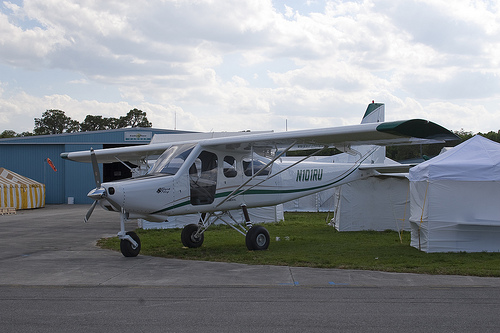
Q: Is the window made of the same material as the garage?
A: No, the window is made of glass and the garage is made of metal.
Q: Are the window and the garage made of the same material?
A: No, the window is made of glass and the garage is made of metal.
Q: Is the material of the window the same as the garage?
A: No, the window is made of glass and the garage is made of metal.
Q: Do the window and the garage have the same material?
A: No, the window is made of glass and the garage is made of metal.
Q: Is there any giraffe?
A: No, there are no giraffes.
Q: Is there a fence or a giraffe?
A: No, there are no giraffes or fences.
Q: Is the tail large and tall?
A: Yes, the tail is large and tall.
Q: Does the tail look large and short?
A: No, the tail is large but tall.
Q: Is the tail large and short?
A: No, the tail is large but tall.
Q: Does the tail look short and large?
A: No, the tail is large but tall.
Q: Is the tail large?
A: Yes, the tail is large.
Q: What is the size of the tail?
A: The tail is large.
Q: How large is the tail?
A: The tail is large.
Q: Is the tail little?
A: No, the tail is large.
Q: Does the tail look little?
A: No, the tail is large.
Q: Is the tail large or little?
A: The tail is large.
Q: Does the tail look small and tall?
A: No, the tail is tall but large.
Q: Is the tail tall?
A: Yes, the tail is tall.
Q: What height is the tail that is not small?
A: The tail is tall.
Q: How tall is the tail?
A: The tail is tall.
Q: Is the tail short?
A: No, the tail is tall.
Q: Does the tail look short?
A: No, the tail is tall.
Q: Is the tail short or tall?
A: The tail is tall.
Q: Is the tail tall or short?
A: The tail is tall.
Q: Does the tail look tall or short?
A: The tail is tall.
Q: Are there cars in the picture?
A: No, there are no cars.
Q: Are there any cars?
A: No, there are no cars.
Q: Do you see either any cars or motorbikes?
A: No, there are no cars or motorbikes.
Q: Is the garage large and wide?
A: Yes, the garage is large and wide.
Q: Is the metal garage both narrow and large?
A: No, the garage is large but wide.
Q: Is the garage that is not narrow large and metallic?
A: Yes, the garage is large and metallic.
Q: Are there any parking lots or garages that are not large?
A: No, there is a garage but it is large.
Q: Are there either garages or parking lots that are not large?
A: No, there is a garage but it is large.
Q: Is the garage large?
A: Yes, the garage is large.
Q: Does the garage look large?
A: Yes, the garage is large.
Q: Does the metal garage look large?
A: Yes, the garage is large.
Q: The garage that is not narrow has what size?
A: The garage is large.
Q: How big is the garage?
A: The garage is large.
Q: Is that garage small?
A: No, the garage is large.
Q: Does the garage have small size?
A: No, the garage is large.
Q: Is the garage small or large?
A: The garage is large.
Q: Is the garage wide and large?
A: Yes, the garage is wide and large.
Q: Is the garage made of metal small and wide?
A: No, the garage is wide but large.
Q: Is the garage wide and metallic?
A: Yes, the garage is wide and metallic.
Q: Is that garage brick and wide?
A: No, the garage is wide but metallic.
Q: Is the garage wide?
A: Yes, the garage is wide.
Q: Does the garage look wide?
A: Yes, the garage is wide.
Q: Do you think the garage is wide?
A: Yes, the garage is wide.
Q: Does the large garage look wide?
A: Yes, the garage is wide.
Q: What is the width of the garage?
A: The garage is wide.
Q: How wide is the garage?
A: The garage is wide.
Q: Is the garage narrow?
A: No, the garage is wide.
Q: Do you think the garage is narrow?
A: No, the garage is wide.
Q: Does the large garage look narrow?
A: No, the garage is wide.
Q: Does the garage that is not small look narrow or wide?
A: The garage is wide.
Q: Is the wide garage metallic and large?
A: Yes, the garage is metallic and large.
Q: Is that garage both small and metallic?
A: No, the garage is metallic but large.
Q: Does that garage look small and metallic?
A: No, the garage is metallic but large.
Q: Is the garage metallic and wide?
A: Yes, the garage is metallic and wide.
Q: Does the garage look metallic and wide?
A: Yes, the garage is metallic and wide.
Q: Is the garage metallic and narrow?
A: No, the garage is metallic but wide.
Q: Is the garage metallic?
A: Yes, the garage is metallic.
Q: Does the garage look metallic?
A: Yes, the garage is metallic.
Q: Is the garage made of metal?
A: Yes, the garage is made of metal.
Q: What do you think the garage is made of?
A: The garage is made of metal.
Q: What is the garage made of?
A: The garage is made of metal.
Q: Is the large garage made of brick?
A: No, the garage is made of metal.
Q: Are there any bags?
A: No, there are no bags.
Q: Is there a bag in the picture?
A: No, there are no bags.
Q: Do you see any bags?
A: No, there are no bags.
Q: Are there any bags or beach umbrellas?
A: No, there are no bags or beach umbrellas.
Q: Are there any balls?
A: No, there are no balls.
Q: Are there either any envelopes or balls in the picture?
A: No, there are no balls or envelopes.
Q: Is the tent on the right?
A: Yes, the tent is on the right of the image.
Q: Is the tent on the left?
A: No, the tent is on the right of the image.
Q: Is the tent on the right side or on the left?
A: The tent is on the right of the image.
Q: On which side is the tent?
A: The tent is on the right of the image.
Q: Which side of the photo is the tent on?
A: The tent is on the right of the image.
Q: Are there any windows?
A: Yes, there is a window.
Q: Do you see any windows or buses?
A: Yes, there is a window.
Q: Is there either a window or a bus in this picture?
A: Yes, there is a window.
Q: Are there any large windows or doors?
A: Yes, there is a large window.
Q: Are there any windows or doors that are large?
A: Yes, the window is large.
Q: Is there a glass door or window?
A: Yes, there is a glass window.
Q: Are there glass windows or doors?
A: Yes, there is a glass window.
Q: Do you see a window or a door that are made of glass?
A: Yes, the window is made of glass.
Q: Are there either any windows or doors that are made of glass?
A: Yes, the window is made of glass.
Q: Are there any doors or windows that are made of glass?
A: Yes, the window is made of glass.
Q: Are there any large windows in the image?
A: Yes, there is a large window.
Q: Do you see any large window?
A: Yes, there is a large window.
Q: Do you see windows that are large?
A: Yes, there is a window that is large.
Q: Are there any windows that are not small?
A: Yes, there is a large window.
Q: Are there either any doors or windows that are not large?
A: No, there is a window but it is large.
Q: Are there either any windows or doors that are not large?
A: No, there is a window but it is large.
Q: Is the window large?
A: Yes, the window is large.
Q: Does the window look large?
A: Yes, the window is large.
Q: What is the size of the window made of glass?
A: The window is large.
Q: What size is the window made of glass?
A: The window is large.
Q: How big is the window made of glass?
A: The window is large.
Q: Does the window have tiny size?
A: No, the window is large.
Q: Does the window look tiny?
A: No, the window is large.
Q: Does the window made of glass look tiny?
A: No, the window is large.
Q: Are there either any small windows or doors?
A: No, there is a window but it is large.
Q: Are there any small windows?
A: No, there is a window but it is large.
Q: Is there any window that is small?
A: No, there is a window but it is large.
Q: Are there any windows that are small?
A: No, there is a window but it is large.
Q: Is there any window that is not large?
A: No, there is a window but it is large.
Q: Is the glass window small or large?
A: The window is large.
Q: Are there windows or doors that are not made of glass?
A: No, there is a window but it is made of glass.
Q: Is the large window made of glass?
A: Yes, the window is made of glass.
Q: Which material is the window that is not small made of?
A: The window is made of glass.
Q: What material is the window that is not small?
A: The window is made of glass.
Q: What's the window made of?
A: The window is made of glass.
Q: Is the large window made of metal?
A: No, the window is made of glass.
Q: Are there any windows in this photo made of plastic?
A: No, there is a window but it is made of glass.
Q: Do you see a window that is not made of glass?
A: No, there is a window but it is made of glass.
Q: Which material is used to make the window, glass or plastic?
A: The window is made of glass.